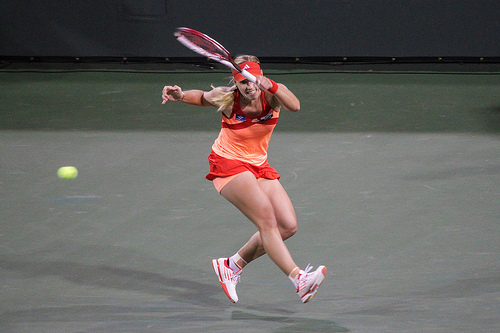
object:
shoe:
[293, 263, 328, 304]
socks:
[228, 257, 240, 273]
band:
[265, 77, 279, 95]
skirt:
[203, 148, 280, 182]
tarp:
[0, 0, 499, 58]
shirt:
[210, 89, 281, 168]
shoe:
[210, 256, 243, 303]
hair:
[208, 54, 262, 114]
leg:
[210, 166, 298, 304]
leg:
[209, 161, 327, 303]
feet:
[293, 264, 328, 304]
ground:
[0, 62, 500, 333]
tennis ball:
[57, 166, 80, 180]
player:
[160, 54, 327, 304]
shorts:
[211, 171, 265, 195]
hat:
[232, 61, 262, 82]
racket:
[172, 26, 261, 87]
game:
[0, 0, 500, 333]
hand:
[256, 75, 273, 91]